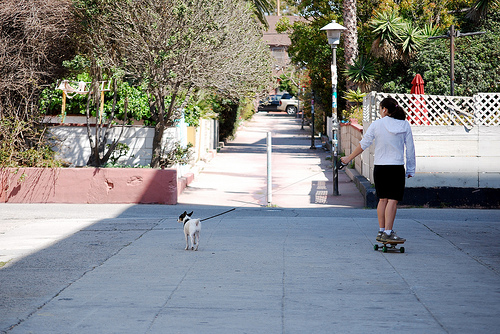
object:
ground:
[181, 117, 371, 210]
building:
[38, 119, 219, 166]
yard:
[0, 168, 196, 205]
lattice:
[361, 91, 500, 127]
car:
[277, 92, 304, 117]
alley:
[176, 111, 376, 208]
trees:
[340, 1, 361, 108]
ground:
[1, 204, 500, 334]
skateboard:
[373, 241, 405, 253]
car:
[256, 95, 283, 113]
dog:
[177, 210, 202, 250]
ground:
[410, 209, 499, 242]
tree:
[84, 0, 274, 171]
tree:
[60, 0, 129, 168]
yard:
[0, 115, 188, 169]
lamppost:
[319, 20, 347, 197]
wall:
[338, 126, 500, 189]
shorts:
[373, 163, 405, 201]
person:
[340, 97, 417, 243]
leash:
[200, 165, 333, 221]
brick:
[0, 149, 215, 204]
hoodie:
[358, 116, 416, 177]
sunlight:
[177, 115, 354, 209]